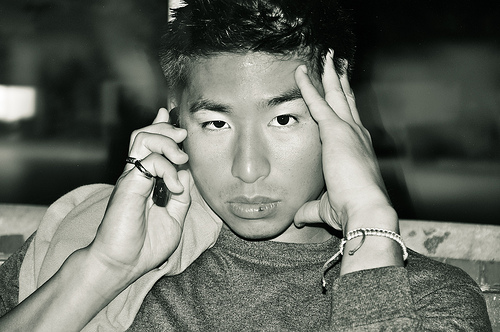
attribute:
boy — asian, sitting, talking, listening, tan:
[130, 16, 436, 308]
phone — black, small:
[146, 118, 180, 205]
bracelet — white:
[342, 222, 413, 250]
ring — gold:
[127, 155, 149, 179]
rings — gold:
[126, 154, 156, 182]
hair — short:
[157, 8, 356, 61]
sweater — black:
[157, 229, 342, 331]